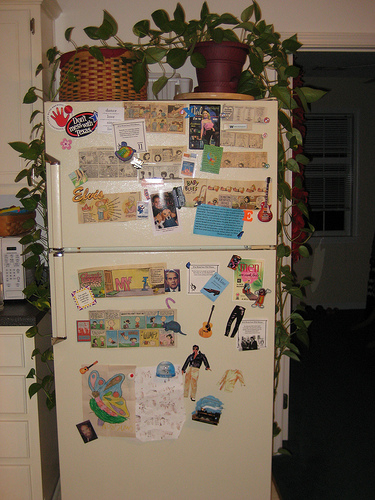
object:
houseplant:
[7, 0, 328, 458]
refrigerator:
[44, 100, 278, 500]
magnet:
[60, 138, 72, 150]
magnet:
[242, 209, 253, 222]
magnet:
[257, 176, 274, 224]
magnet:
[198, 303, 216, 339]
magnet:
[223, 304, 247, 339]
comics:
[78, 263, 167, 298]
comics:
[88, 296, 188, 349]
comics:
[72, 186, 142, 224]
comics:
[220, 129, 268, 149]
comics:
[183, 175, 275, 223]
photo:
[150, 192, 180, 233]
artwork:
[78, 359, 136, 438]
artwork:
[135, 360, 187, 442]